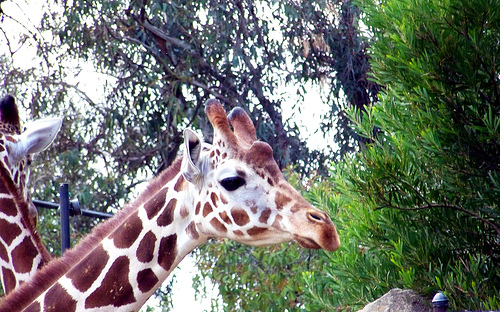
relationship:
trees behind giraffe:
[277, 28, 428, 141] [0, 96, 343, 311]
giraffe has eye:
[0, 96, 343, 311] [218, 175, 249, 194]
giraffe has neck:
[0, 96, 343, 311] [0, 185, 205, 310]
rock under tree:
[347, 281, 441, 309] [216, 2, 498, 307]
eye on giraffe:
[218, 175, 249, 194] [0, 96, 343, 311]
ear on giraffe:
[182, 125, 201, 171] [0, 96, 343, 311]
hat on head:
[429, 291, 449, 306] [427, 298, 449, 310]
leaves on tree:
[202, 0, 499, 310] [190, 0, 499, 311]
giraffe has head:
[0, 96, 343, 311] [169, 85, 349, 260]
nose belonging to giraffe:
[304, 207, 339, 249] [0, 96, 343, 311]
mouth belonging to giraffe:
[285, 229, 342, 254] [0, 96, 343, 311]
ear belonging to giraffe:
[24, 114, 66, 154] [0, 92, 62, 294]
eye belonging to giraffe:
[218, 175, 248, 194] [24, 60, 327, 309]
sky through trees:
[1, 0, 370, 99] [118, 2, 263, 96]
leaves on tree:
[361, 6, 498, 292] [290, 7, 482, 270]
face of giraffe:
[168, 67, 351, 277] [110, 110, 309, 264]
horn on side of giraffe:
[201, 94, 235, 152] [0, 96, 343, 311]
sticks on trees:
[374, 157, 499, 244] [356, 42, 493, 261]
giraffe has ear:
[0, 96, 343, 311] [181, 125, 203, 185]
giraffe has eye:
[0, 96, 343, 311] [203, 170, 267, 199]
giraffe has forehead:
[29, 116, 316, 263] [233, 129, 299, 191]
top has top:
[428, 288, 451, 304] [428, 290, 452, 304]